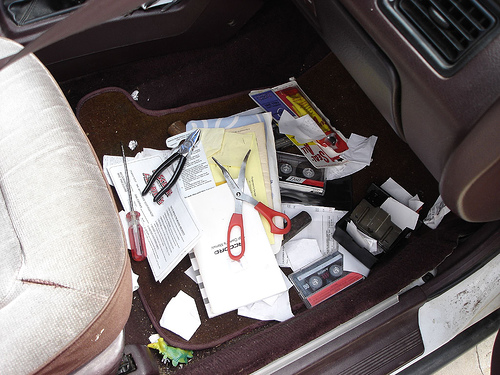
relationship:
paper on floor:
[248, 72, 365, 179] [54, 49, 477, 374]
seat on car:
[1, 24, 137, 373] [1, 22, 142, 373]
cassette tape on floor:
[288, 247, 363, 310] [114, 63, 440, 317]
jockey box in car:
[310, 0, 405, 143] [1, 0, 498, 373]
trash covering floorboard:
[123, 51, 418, 363] [50, 11, 483, 371]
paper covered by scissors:
[160, 288, 203, 342] [210, 148, 290, 260]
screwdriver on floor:
[116, 140, 147, 262] [58, 50, 440, 372]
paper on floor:
[160, 288, 203, 342] [53, 20, 447, 368]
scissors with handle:
[210, 148, 290, 260] [256, 202, 288, 233]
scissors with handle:
[210, 148, 290, 260] [223, 215, 245, 259]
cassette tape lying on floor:
[277, 141, 327, 197] [94, 39, 459, 362]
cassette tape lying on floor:
[291, 247, 363, 302] [94, 39, 459, 362]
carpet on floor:
[75, 79, 447, 352] [54, 49, 476, 373]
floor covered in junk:
[54, 49, 476, 373] [106, 88, 462, 346]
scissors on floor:
[210, 148, 290, 260] [54, 49, 477, 374]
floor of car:
[54, 49, 477, 374] [1, 0, 498, 373]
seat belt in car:
[2, 0, 155, 77] [1, 0, 498, 373]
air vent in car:
[384, 2, 498, 72] [1, 0, 498, 373]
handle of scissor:
[226, 202, 290, 261] [212, 150, 289, 262]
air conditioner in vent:
[402, 8, 486, 50] [453, 4, 488, 32]